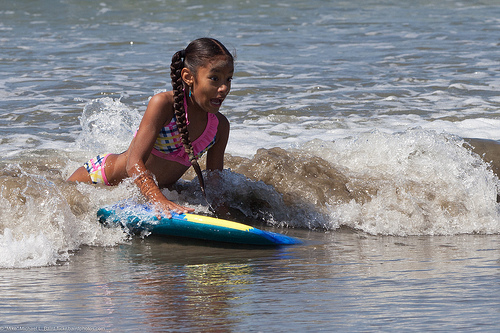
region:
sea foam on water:
[6, 6, 497, 138]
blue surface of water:
[3, 2, 496, 130]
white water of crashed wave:
[333, 133, 495, 230]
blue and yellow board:
[96, 203, 293, 248]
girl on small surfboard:
[61, 38, 233, 211]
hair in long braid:
[168, 50, 204, 182]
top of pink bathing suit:
[154, 102, 217, 164]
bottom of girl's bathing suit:
[81, 152, 113, 186]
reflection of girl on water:
[141, 242, 248, 332]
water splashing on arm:
[121, 171, 163, 228]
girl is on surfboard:
[95, 34, 279, 248]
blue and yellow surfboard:
[70, 183, 290, 277]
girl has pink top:
[124, 110, 235, 165]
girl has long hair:
[178, 47, 192, 215]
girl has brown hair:
[164, 18, 259, 205]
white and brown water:
[261, 120, 428, 234]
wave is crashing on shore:
[247, 133, 464, 234]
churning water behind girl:
[250, 3, 415, 103]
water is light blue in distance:
[248, 8, 403, 102]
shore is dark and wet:
[297, 247, 442, 328]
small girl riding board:
[83, 20, 270, 221]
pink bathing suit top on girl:
[117, 75, 220, 163]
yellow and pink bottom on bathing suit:
[83, 138, 113, 195]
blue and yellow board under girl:
[145, 183, 294, 258]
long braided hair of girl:
[134, 44, 199, 146]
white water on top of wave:
[297, 117, 450, 224]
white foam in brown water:
[299, 67, 391, 105]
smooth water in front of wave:
[320, 257, 456, 332]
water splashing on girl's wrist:
[126, 159, 161, 216]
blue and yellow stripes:
[154, 112, 175, 169]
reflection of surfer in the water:
[130, 237, 273, 332]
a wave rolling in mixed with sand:
[3, 107, 493, 274]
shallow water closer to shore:
[1, 232, 496, 332]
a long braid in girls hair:
[158, 33, 238, 200]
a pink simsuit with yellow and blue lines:
[84, 92, 219, 187]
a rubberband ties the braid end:
[179, 134, 204, 169]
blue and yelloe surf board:
[98, 195, 303, 255]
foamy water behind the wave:
[398, 113, 498, 134]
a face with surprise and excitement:
[157, 38, 236, 120]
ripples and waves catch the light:
[0, 10, 499, 112]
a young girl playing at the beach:
[47, 28, 421, 255]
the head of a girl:
[173, 29, 236, 116]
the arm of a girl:
[130, 92, 191, 222]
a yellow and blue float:
[100, 180, 320, 260]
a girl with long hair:
[171, 29, 243, 203]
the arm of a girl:
[204, 113, 240, 178]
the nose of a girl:
[216, 83, 230, 94]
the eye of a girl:
[206, 70, 219, 82]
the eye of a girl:
[225, 70, 234, 87]